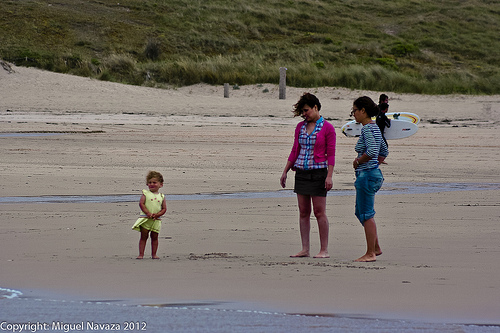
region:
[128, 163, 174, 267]
A toddler standing on a beach.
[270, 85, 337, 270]
A woman in a pink shirt and mini skirt.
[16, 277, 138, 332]
Water meeting the shore.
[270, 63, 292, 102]
A pillar in the distance.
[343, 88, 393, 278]
A woman wearing blue jeans.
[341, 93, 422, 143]
People carry surfboards in the distance.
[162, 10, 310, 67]
A green, grassy field.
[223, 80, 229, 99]
A small pillar in the background.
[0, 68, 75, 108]
A large mound of dirt.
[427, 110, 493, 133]
A patch of brown sand.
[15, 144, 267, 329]
young girl at the beach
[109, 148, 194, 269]
young girl wearing a dress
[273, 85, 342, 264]
lady wearing a plaid shirt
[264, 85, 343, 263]
lady wearing a pink cardigan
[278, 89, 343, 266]
lady wearing black shorts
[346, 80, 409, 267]
girl wearing long sleep stripe shirt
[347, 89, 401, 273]
girl wearing denim jeans rolled up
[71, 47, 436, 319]
family at the beach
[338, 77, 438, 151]
two people holding surfboard each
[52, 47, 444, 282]
Everyone standing on the sand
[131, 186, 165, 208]
green shirt of little girl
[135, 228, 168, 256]
legs of the little girl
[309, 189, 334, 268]
left leg of woman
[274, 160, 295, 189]
right hand of woman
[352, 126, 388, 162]
striped shirt of girl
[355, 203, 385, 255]
left leg of girl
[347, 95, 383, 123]
head of the girl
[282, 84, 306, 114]
blowing hair of the girl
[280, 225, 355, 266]
feet in the sand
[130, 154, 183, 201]
head of little girl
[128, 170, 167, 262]
small girl on the beach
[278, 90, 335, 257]
woman in a pink sweater next to child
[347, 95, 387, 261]
woman in blue striped shirt on the beach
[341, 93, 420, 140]
people carrying surfboards in the background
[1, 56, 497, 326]
a wet, sandy beach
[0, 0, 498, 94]
grass behind the beach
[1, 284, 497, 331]
calm ocean in front of the people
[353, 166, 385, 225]
rolled up blue jeans on woman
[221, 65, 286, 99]
wooden posts behind people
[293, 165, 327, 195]
black skirt on woman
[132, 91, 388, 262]
Group gathers on the beach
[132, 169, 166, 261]
Toddler watches the water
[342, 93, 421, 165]
Surfer walks the beach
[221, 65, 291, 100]
Poles in the sand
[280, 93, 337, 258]
Woman watches toddler on the beach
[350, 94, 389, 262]
Girl stands on the beach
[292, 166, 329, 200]
Short black skirt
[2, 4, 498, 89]
Green meadow near the beach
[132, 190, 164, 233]
Little lime green sundress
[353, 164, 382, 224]
Rolled up denim capris